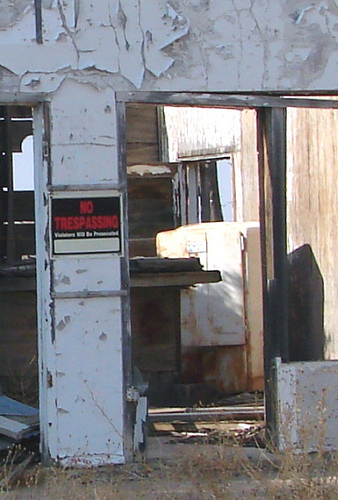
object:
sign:
[48, 187, 121, 257]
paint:
[1, 1, 337, 465]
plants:
[1, 385, 338, 500]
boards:
[239, 100, 335, 394]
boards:
[145, 395, 268, 438]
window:
[9, 132, 38, 191]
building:
[0, 1, 338, 466]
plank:
[5, 259, 202, 272]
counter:
[2, 257, 225, 413]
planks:
[3, 192, 34, 221]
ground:
[0, 397, 338, 500]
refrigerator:
[155, 221, 268, 394]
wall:
[49, 92, 124, 468]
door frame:
[110, 86, 279, 464]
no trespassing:
[54, 202, 120, 231]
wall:
[1, 2, 336, 94]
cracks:
[53, 0, 95, 69]